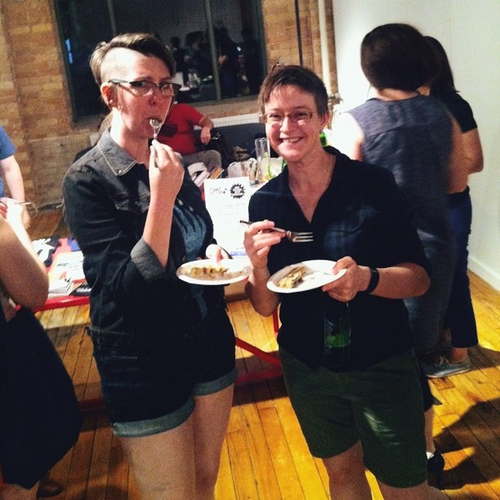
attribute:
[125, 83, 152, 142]
woman — eating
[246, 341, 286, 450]
floor — hardwood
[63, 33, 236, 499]
woman — the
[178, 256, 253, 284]
plate — white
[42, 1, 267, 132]
window — big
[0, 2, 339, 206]
wall — brick, back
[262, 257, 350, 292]
plate — white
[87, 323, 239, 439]
shorts — blue, jean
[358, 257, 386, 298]
wristband — black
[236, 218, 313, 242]
fork — silver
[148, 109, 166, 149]
utensil — eating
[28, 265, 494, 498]
floor — light colored, wood, wooden, brown, the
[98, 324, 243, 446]
shorts — the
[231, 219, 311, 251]
fork — the, metal, silver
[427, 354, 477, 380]
shoe — blue, the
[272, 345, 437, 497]
shorts — the, green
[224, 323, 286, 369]
leg — the, table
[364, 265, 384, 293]
watch — the, black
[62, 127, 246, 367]
shirt — the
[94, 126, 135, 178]
collar — a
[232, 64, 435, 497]
woman — the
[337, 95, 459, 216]
shirt — the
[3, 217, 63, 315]
elbow — the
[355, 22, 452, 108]
hair — her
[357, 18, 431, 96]
hair — her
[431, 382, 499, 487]
shadow — a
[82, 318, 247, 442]
shorts — cuffed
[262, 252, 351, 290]
plate — the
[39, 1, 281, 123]
window — the, big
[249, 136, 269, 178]
glass — the, tall